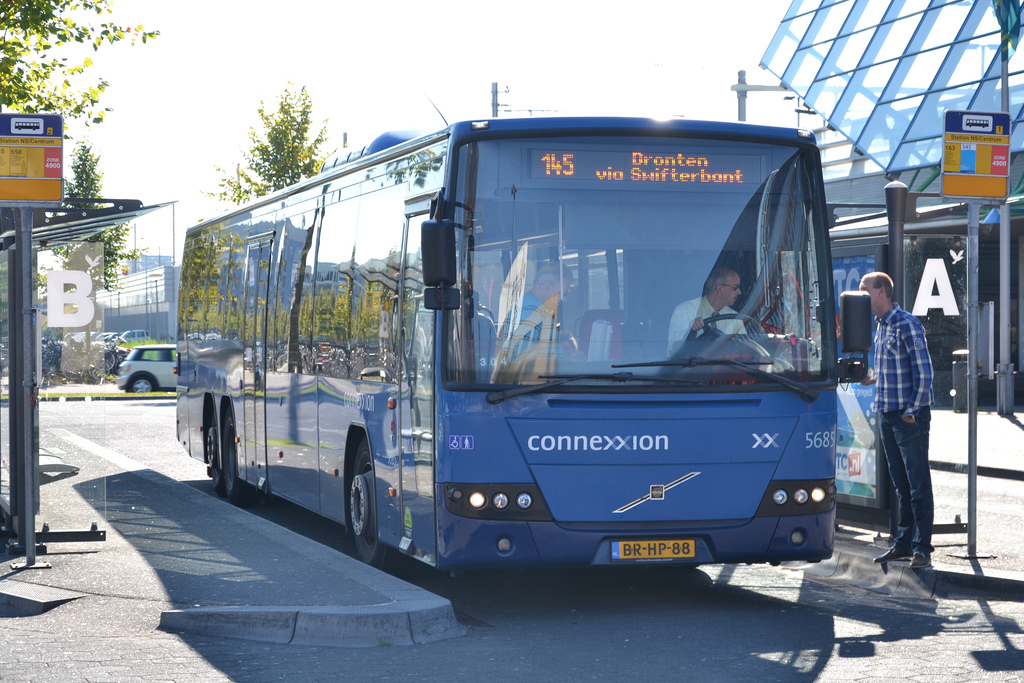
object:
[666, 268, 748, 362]
bus driver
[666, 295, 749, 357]
shirt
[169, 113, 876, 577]
bus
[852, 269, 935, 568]
guy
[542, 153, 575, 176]
number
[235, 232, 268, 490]
door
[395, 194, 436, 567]
door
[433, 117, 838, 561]
front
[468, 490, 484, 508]
light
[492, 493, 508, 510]
light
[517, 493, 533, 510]
light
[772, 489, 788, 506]
light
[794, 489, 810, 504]
light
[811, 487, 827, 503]
light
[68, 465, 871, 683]
shadow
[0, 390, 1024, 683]
street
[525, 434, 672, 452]
word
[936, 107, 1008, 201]
sign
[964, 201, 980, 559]
post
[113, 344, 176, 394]
car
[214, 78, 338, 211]
tree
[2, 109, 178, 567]
bus stop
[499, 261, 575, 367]
person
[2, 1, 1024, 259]
sky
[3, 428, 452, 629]
walkway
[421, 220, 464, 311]
side mirror